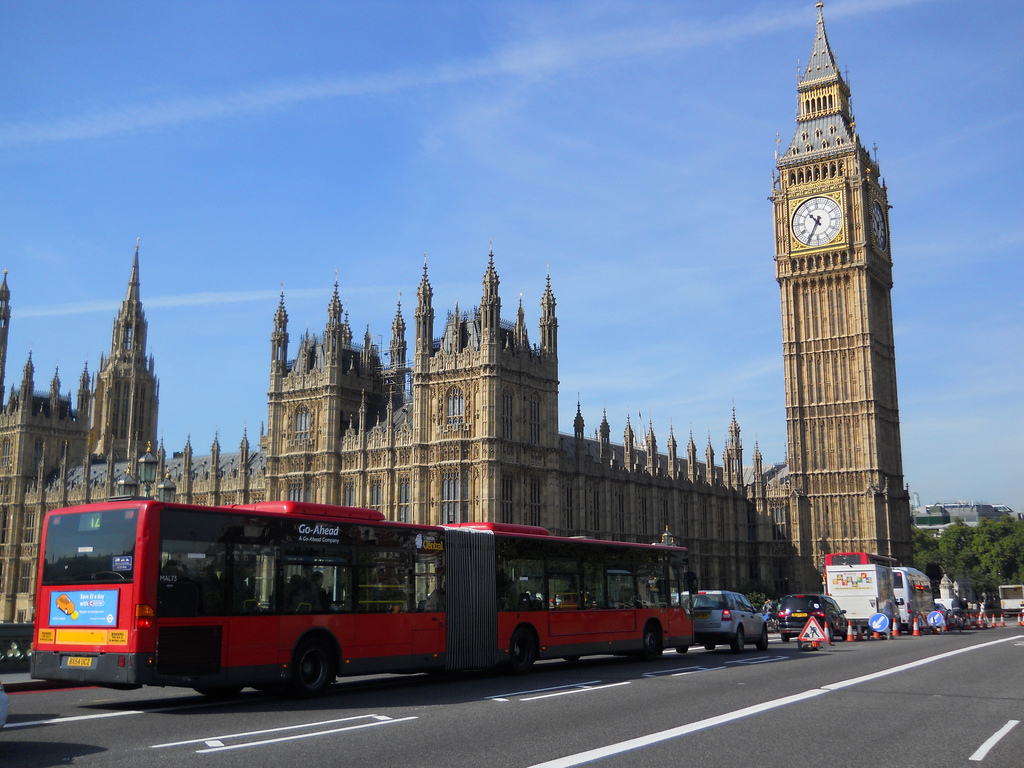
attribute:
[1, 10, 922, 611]
building — tan, large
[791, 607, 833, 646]
sign — warning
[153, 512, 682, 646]
window — large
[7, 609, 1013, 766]
road — orange, white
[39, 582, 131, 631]
advertising — blue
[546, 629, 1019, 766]
line — white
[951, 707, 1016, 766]
line — white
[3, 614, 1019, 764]
street — solid, white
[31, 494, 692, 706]
bus — double long, commuter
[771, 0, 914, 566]
tower — tan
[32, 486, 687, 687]
bus — long, red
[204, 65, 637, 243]
clouds — white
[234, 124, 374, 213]
sky — blue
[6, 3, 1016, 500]
clouds — white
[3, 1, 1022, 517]
sky — blue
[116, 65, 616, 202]
clouds — white